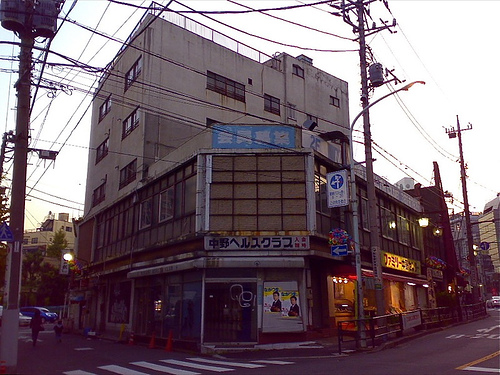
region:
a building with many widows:
[88, 20, 431, 356]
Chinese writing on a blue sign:
[207, 121, 297, 148]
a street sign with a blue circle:
[315, 165, 350, 211]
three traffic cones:
[116, 322, 176, 347]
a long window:
[192, 62, 247, 107]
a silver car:
[482, 290, 497, 311]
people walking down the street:
[21, 306, 66, 344]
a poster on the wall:
[257, 278, 302, 338]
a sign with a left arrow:
[320, 241, 351, 257]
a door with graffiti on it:
[202, 280, 266, 349]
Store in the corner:
[68, 117, 469, 359]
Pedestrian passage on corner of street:
[78, 341, 283, 373]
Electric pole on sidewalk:
[348, 10, 399, 374]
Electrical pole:
[440, 107, 498, 318]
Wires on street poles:
[22, 4, 424, 78]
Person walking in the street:
[25, 301, 47, 349]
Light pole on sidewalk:
[330, 70, 430, 364]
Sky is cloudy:
[2, 8, 489, 202]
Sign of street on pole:
[318, 162, 353, 212]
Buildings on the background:
[15, 212, 79, 324]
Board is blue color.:
[211, 122, 301, 150]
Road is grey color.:
[404, 348, 438, 370]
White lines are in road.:
[73, 356, 157, 371]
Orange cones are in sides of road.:
[107, 323, 200, 353]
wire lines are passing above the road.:
[6, 33, 128, 141]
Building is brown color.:
[148, 63, 192, 107]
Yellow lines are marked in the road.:
[445, 341, 499, 369]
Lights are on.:
[393, 203, 443, 307]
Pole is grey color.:
[317, 164, 365, 266]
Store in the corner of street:
[196, 229, 327, 357]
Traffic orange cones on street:
[134, 317, 182, 359]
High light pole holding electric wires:
[330, 4, 384, 355]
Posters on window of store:
[257, 279, 307, 337]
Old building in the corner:
[65, 11, 461, 358]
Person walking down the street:
[23, 300, 54, 355]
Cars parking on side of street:
[9, 301, 62, 328]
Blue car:
[19, 301, 59, 322]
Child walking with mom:
[45, 314, 70, 348]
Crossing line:
[61, 347, 278, 373]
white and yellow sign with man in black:
[261, 285, 307, 325]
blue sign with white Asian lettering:
[210, 120, 302, 152]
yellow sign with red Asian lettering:
[376, 245, 433, 274]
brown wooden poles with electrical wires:
[1, 0, 498, 370]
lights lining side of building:
[325, 207, 452, 344]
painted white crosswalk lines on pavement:
[53, 350, 303, 372]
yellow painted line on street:
[449, 345, 499, 371]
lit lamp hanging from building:
[54, 245, 80, 270]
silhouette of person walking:
[27, 308, 52, 346]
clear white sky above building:
[4, 0, 498, 227]